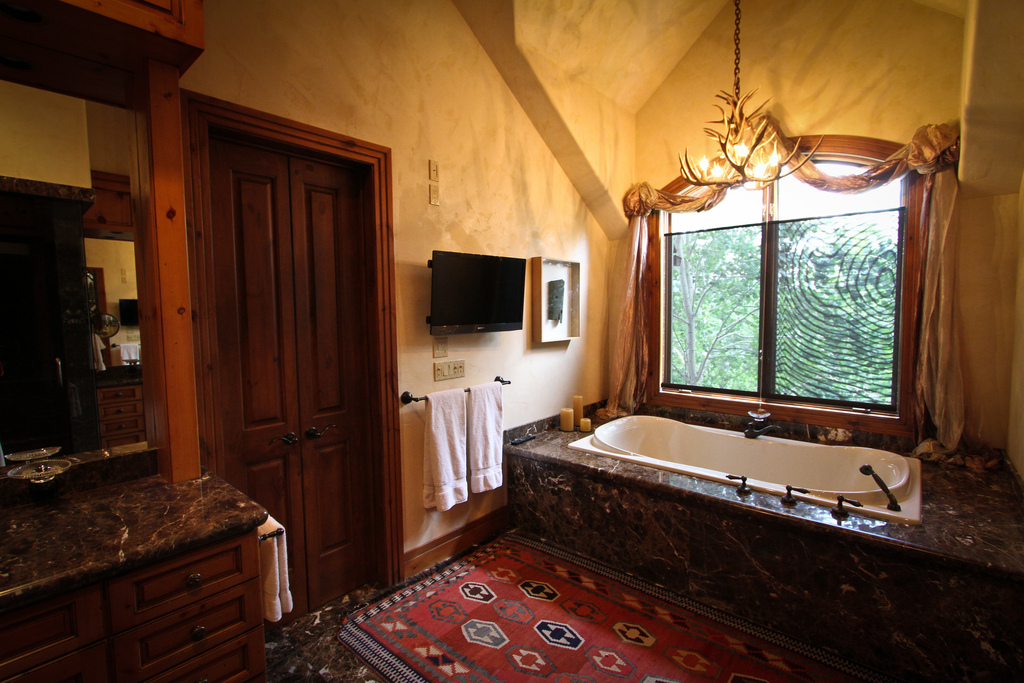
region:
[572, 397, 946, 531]
a white bath tub with fixtures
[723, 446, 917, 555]
a faucet and fixtures for a tub filler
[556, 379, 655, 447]
candles set next to a tub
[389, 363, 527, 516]
towels hanging from a towel rod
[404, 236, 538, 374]
a small LCD TV mounted to the wall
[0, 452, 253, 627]
a granite bathroom top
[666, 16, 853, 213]
a decorative antler chandelier hanging from a chain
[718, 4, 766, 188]
a chain suspending a chandelier from the ceiling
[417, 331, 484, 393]
several wall sockets and outlets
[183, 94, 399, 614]
the door to this bathroom is a double, dark wood door.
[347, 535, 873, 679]
a red and black mat with Native American tribal designs on it lays next to the tub.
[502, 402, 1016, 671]
The counter border around the tub is a dark stone, possibly granite.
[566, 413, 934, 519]
The bathtub is mounted inside a counter that fills the end of the room.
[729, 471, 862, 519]
three rustic looking faucet controls sit on the counter.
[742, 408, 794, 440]
the main faucet is on the side of the tub by the window.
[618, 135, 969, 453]
A window with an arched frame on top and an elaborate window treatment sits behind the tub.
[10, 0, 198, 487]
There is a very large mirror with a rustic frame on the other side of the door.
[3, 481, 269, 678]
the counter and vanity are made of the same dark granite and dark wood.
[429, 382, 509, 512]
two white towels hang on the rack by the tub.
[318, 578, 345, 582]
Sunlight is coming in through the window.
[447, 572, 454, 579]
Sunlight is coming in through the window.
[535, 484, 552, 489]
Sunlight is coming in through the window.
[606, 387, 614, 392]
Sunlight is coming in through the window.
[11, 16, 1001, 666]
elegant bathroom with rustic touches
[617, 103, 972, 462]
knotted and draped fabric surrounding window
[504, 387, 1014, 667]
dark stone encasing white bathtub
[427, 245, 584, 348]
dark-screened television next to textured artwork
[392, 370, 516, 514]
white towels hanging side by side from rack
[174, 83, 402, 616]
wide wooden door with carved rectangular panels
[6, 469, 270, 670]
dark stone vanity with wooden drawers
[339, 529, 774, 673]
red and black rug with symbolic pattern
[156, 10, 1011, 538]
angled walls and ceiling over bathtub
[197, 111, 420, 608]
A wooden double door.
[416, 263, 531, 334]
A flat screen television.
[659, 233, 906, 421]
A double window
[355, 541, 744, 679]
A multi-colored area rug.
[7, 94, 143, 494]
A mirror near the door.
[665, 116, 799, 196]
Several deer antlers above the window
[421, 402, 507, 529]
White towels hanging from towel bar.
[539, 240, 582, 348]
Item in shadow box.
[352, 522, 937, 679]
red patterned carpet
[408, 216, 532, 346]
black tv on wall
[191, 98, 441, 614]
dark wooden door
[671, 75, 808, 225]
antler chandelier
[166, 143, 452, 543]
a large wooden door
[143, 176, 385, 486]
a brown wooden door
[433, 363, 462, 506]
a towl is hanging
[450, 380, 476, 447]
a towl is hanging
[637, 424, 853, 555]
a white bathtub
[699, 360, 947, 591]
a bathtub is white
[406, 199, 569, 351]
a tv on the wall